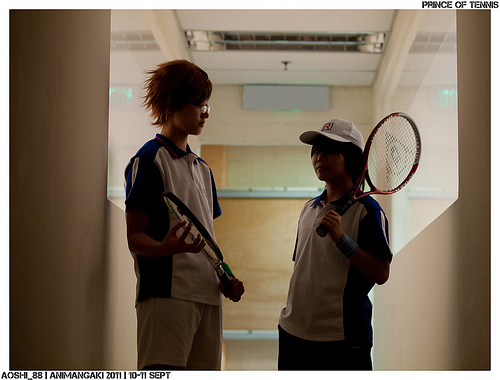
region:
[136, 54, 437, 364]
Peoples holding the tennis racket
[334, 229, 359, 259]
A person wearing wrist band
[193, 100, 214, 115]
A person wearing specs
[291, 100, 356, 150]
A person wearing white color hat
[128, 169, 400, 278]
Peoples wearing white and blue color t-shirt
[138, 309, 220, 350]
A person wearing cream color half trouser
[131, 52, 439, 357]
Peoples standing in the building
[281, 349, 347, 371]
A person wearing black color pant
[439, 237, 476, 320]
Cream color wall of the building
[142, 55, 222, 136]
Head of the person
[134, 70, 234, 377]
the girl has glasses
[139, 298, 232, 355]
the shorts are white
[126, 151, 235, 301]
the shirt is white and blue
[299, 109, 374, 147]
the hat is white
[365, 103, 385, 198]
frame racket is red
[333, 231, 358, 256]
the wristband is blue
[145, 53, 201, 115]
the hair is brown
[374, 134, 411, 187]
symbol is on the racket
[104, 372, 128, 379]
the photo was taken in 2011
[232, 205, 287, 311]
the surface is brown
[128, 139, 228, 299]
A blue and gray jersey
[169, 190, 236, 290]
A tennis racket in the photo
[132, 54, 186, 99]
Brown hair in the photo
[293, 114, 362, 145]
A white cap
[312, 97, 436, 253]
A woman holding a tennis racket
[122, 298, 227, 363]
White shorts in the photo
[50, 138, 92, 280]
A pillar in the building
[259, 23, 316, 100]
Ceiling in the photo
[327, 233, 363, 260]
A wrist band in the photo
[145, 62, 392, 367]
Two tennis players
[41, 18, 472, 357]
tennis players are in a hallway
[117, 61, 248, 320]
the boy is holding a tennis racket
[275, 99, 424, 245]
the boy is holding a tennis racket on his shoulder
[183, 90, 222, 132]
the boy is wearing eyeglasses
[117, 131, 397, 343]
the boys have blue and white shirts on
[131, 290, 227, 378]
khaki shorts are on the player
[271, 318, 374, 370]
dark shorts are on the boy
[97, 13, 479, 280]
windows are in the hallway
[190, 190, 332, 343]
plywood is on the wall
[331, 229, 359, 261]
a gray wrist band is on the boy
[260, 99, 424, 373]
person holding a tennis racket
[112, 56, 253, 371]
person holding a tennis racket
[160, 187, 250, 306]
tennis racket being held by a person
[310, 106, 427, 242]
tennis racket being held by a person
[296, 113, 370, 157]
white hat with red and black logo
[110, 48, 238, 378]
person with red hair and white shirt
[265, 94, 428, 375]
person wearing a white hat and shirt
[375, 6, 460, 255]
large window behind the people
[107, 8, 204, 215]
large window behind the people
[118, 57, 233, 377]
person holding racket wearing glasses